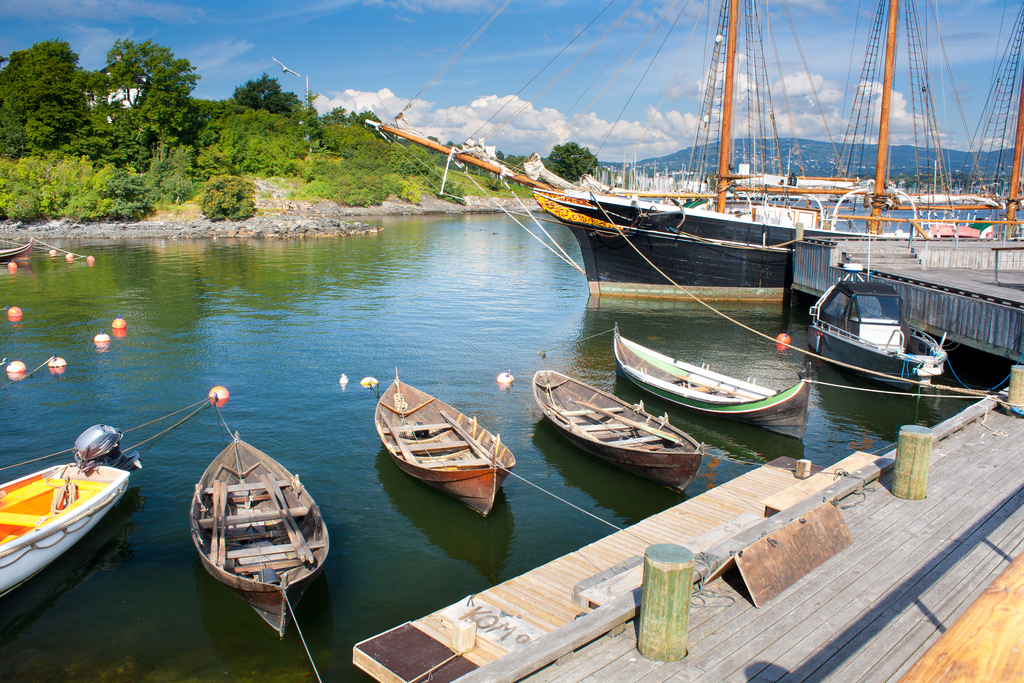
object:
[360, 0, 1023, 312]
boat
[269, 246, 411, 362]
water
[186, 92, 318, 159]
land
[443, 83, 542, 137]
clouds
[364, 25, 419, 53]
blue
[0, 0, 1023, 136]
blue sky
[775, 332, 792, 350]
orange and white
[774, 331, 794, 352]
balls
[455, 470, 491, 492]
red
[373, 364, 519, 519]
canoe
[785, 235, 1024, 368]
dock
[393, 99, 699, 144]
fluffy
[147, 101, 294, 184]
bushes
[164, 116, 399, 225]
hill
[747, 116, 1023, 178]
distance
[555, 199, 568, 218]
yellow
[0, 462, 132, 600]
boat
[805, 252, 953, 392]
small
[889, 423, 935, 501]
short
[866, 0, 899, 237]
post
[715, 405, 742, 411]
green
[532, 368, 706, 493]
canoe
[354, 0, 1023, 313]
large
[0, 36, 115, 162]
trees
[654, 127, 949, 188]
mountain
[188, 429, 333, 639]
boats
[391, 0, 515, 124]
wires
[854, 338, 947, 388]
motor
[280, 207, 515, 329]
surface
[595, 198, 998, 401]
rope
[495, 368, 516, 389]
bouys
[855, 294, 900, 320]
window